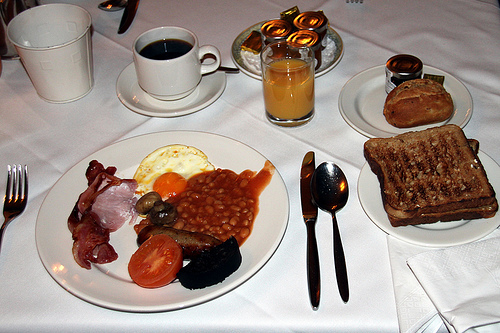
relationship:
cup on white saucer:
[132, 25, 220, 101] [116, 79, 225, 117]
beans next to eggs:
[181, 167, 261, 233] [132, 139, 218, 199]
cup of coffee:
[132, 25, 219, 100] [139, 39, 193, 59]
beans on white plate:
[165, 169, 258, 243] [102, 117, 151, 166]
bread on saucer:
[365, 124, 497, 229] [355, 165, 388, 237]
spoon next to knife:
[309, 158, 357, 303] [299, 148, 324, 310]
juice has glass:
[266, 59, 312, 119] [258, 39, 325, 125]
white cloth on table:
[368, 3, 480, 50] [11, 2, 488, 329]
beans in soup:
[165, 169, 258, 243] [64, 141, 277, 288]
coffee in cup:
[153, 42, 171, 52] [125, 17, 227, 104]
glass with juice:
[258, 49, 318, 89] [273, 78, 304, 120]